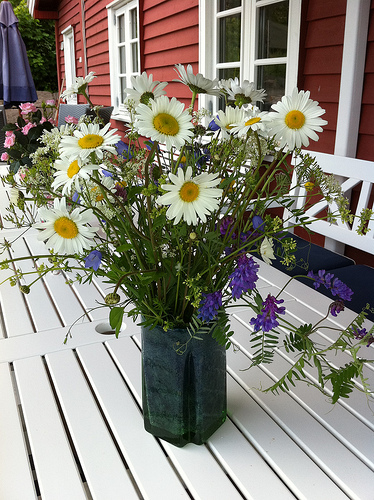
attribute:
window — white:
[102, 1, 145, 109]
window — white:
[189, 5, 303, 170]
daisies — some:
[76, 85, 311, 274]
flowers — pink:
[4, 95, 44, 163]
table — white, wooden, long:
[16, 173, 373, 499]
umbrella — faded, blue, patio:
[2, 4, 36, 114]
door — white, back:
[53, 25, 81, 96]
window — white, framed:
[99, 6, 152, 112]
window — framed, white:
[206, 10, 320, 138]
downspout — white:
[327, 2, 373, 146]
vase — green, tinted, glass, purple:
[140, 310, 228, 448]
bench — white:
[278, 145, 373, 287]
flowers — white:
[221, 85, 343, 150]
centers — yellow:
[241, 110, 303, 131]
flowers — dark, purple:
[312, 269, 357, 316]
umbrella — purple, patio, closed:
[2, 4, 29, 101]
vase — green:
[146, 312, 227, 435]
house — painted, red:
[59, 6, 373, 299]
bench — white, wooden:
[259, 148, 373, 328]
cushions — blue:
[278, 235, 373, 317]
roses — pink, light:
[4, 101, 42, 156]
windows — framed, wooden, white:
[101, 5, 145, 92]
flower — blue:
[309, 263, 355, 308]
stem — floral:
[148, 269, 161, 311]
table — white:
[40, 264, 372, 493]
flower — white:
[160, 164, 223, 226]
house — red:
[52, 41, 372, 263]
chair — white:
[254, 155, 373, 324]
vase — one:
[135, 304, 224, 449]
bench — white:
[271, 142, 373, 282]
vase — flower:
[135, 302, 222, 436]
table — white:
[6, 195, 373, 488]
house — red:
[62, 42, 372, 280]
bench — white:
[274, 141, 369, 247]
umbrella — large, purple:
[1, 41, 32, 112]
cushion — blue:
[265, 229, 372, 302]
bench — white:
[270, 140, 372, 309]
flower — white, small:
[161, 167, 227, 230]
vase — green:
[138, 309, 223, 438]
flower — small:
[195, 282, 218, 316]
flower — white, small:
[263, 92, 323, 151]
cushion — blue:
[277, 233, 372, 337]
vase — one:
[146, 319, 228, 444]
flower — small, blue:
[76, 247, 99, 273]